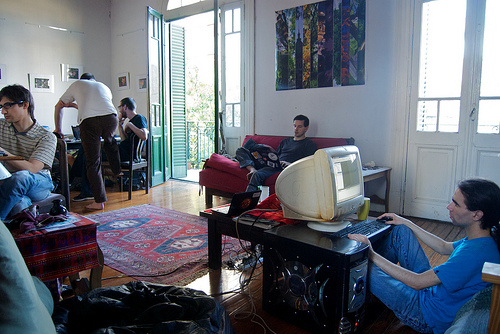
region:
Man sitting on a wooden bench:
[0, 84, 57, 216]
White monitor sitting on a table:
[274, 146, 365, 233]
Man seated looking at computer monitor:
[347, 178, 498, 332]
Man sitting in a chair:
[117, 95, 149, 165]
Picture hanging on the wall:
[276, 2, 367, 90]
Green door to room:
[147, 5, 174, 185]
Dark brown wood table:
[198, 200, 376, 330]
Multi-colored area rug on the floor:
[70, 201, 254, 287]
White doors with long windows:
[402, 0, 496, 222]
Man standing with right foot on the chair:
[52, 72, 119, 211]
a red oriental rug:
[82, 211, 232, 279]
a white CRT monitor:
[269, 143, 372, 229]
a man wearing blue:
[380, 176, 498, 332]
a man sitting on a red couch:
[207, 110, 316, 187]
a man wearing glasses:
[0, 80, 60, 217]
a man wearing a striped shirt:
[0, 82, 56, 216]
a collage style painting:
[270, 0, 365, 93]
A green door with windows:
[142, 6, 189, 188]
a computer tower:
[260, 240, 371, 332]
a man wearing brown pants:
[59, 67, 124, 209]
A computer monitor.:
[273, 145, 365, 230]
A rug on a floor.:
[81, 203, 253, 283]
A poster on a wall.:
[273, 0, 367, 90]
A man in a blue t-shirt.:
[419, 235, 496, 329]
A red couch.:
[196, 134, 356, 205]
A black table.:
[207, 198, 387, 333]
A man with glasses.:
[0, 84, 55, 216]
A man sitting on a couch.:
[250, 115, 316, 210]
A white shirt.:
[61, 79, 116, 123]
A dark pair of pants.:
[74, 115, 119, 203]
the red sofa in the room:
[198, 133, 354, 203]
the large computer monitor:
[274, 145, 364, 230]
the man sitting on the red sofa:
[236, 113, 314, 195]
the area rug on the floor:
[78, 202, 251, 286]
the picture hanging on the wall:
[275, 0, 371, 90]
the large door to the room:
[148, 5, 176, 187]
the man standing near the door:
[53, 73, 123, 209]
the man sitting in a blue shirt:
[346, 179, 498, 330]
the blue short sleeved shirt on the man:
[420, 234, 499, 329]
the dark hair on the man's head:
[457, 180, 499, 230]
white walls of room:
[2, 1, 491, 221]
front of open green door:
[145, 8, 212, 187]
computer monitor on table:
[217, 144, 384, 258]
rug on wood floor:
[76, 179, 254, 291]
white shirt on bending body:
[61, 73, 111, 125]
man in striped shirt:
[3, 85, 53, 172]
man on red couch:
[202, 113, 354, 205]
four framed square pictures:
[26, 61, 149, 91]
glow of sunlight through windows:
[416, 3, 497, 133]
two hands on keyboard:
[344, 211, 402, 243]